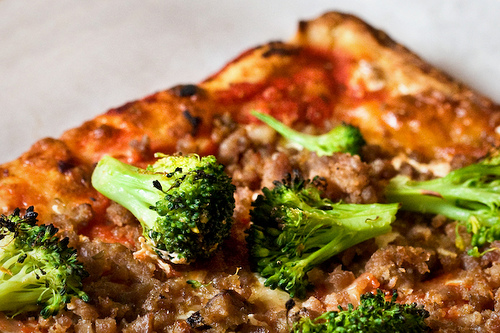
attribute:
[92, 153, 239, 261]
broccoli — green, piece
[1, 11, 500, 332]
pizza — red, oily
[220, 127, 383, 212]
meat — sausage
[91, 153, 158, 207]
stems — green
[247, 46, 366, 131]
sauce — red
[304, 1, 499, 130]
crust — black, brown, spot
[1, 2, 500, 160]
plate — white, clean